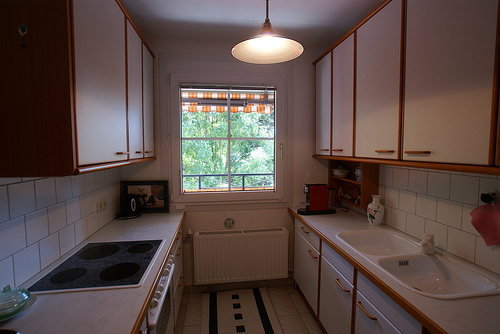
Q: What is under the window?
A: A radiator.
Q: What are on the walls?
A: Wood cabinets.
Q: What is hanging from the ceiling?
A: Light.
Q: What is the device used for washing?
A: Kitchen sink.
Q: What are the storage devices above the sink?
A: Cabinets.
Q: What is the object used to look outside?
A: Window.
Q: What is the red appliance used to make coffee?
A: Coffee pot.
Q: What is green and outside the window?
A: Trees.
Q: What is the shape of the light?
A: A circle.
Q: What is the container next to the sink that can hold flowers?
A: Vase.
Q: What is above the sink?
A: Cabinets.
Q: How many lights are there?
A: 1.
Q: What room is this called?
A: Kitchen.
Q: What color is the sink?
A: White.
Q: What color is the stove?
A: Black.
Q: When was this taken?
A: Daytime.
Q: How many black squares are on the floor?
A: 4.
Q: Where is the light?
A: The ceiling.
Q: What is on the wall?
A: White tile.